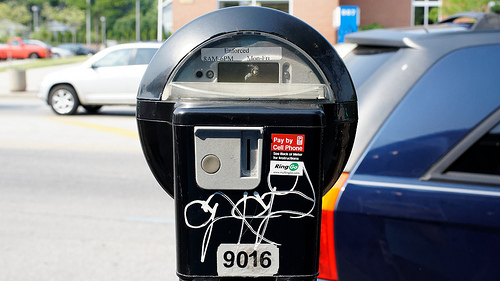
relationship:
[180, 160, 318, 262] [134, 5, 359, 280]
graffiti on meter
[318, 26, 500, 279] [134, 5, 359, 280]
car next to meter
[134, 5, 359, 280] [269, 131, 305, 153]
meter has option to pay by cell phone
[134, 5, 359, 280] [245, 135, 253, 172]
meter has coin slot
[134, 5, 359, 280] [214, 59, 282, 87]
meter has display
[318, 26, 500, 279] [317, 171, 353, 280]
car has hindlight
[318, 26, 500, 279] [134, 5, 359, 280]
car beside meter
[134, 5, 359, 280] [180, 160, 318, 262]
meter has graffiti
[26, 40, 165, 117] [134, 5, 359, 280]
car behind meter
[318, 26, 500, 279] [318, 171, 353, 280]
car has tail light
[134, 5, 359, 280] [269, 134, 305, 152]
meter has pay by cell phone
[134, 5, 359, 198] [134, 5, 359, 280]
circle on top of meter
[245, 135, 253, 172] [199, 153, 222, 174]
coin slot beside button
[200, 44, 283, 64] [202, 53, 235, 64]
label has times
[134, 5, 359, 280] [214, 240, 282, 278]
meter has identification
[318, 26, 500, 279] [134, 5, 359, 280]
car by meter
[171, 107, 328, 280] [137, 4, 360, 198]
box supporting top of meter